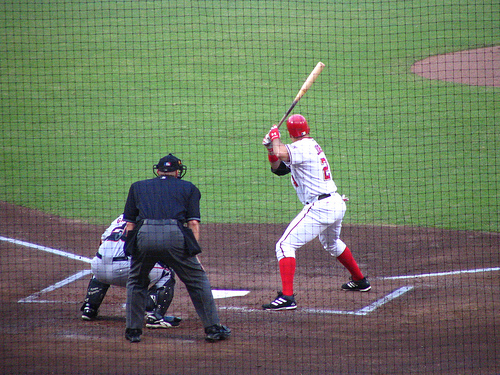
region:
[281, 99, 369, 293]
baseball player on field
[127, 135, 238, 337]
baseball player on field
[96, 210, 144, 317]
baseball player on field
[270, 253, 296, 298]
red sock on baseball player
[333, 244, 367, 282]
red sock on baseball player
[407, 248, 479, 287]
white line on clay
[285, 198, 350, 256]
white pants on baseball player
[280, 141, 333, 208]
white shirt on baseball player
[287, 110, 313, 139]
red helmet on baseball player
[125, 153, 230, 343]
umpire standing behind batter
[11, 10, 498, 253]
green grass on field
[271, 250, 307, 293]
tall red sock on player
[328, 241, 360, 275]
tall red sock on player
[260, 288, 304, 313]
black cleat on baseball player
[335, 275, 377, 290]
black cleat on baseball player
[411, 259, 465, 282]
white line on clay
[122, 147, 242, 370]
umpire on baseball field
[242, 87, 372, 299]
batter standing at home plate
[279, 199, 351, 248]
white pants on player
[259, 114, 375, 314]
A baseball player wearing red and white.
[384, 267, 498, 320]
Baseball field white markings.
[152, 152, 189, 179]
An umpire's black hat.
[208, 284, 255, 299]
Home base plate.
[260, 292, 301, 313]
A black and white shoe.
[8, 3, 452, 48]
Green grass on the field.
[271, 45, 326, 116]
A beige baseball bat.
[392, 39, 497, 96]
The pitcher's mound.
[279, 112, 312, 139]
A shiny red helmet.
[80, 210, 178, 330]
A man squatting on his knees.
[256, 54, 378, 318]
baseball player holding a bat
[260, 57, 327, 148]
baseball bat in a players hands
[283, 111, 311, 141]
helmet on a persons head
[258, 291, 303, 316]
black and white shoe on a persons foot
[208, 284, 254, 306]
home plate on a baseball field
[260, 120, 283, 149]
red and white gloves on a persons hands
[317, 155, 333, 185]
number on a players uniform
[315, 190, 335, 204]
belt on a players uniform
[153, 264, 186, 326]
shin guard on a catchers leg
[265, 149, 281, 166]
red wrist band on a persons wrist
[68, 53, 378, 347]
Baseball players playing baseball in ball field